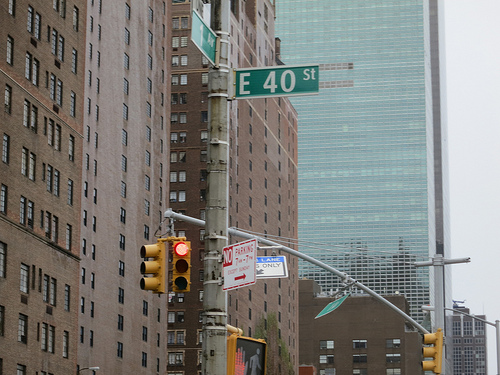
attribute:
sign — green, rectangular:
[231, 60, 323, 103]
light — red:
[172, 238, 191, 260]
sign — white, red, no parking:
[216, 234, 262, 293]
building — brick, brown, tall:
[2, 1, 91, 372]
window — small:
[69, 46, 80, 75]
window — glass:
[373, 265, 382, 273]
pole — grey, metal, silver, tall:
[197, 0, 233, 372]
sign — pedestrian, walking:
[227, 334, 269, 374]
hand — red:
[232, 344, 248, 373]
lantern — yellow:
[138, 233, 168, 297]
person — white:
[246, 343, 262, 373]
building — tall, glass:
[274, 3, 455, 374]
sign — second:
[186, 3, 221, 70]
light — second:
[420, 324, 446, 373]